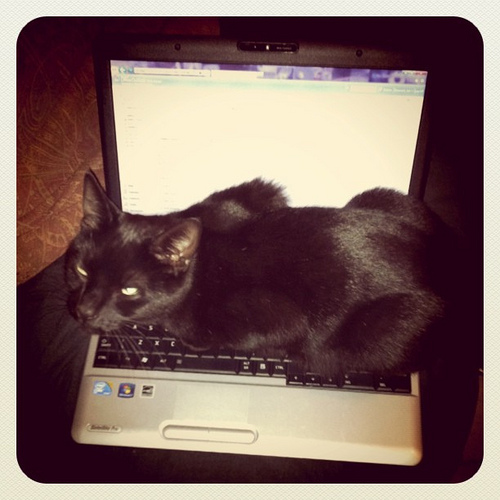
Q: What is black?
A: Cat.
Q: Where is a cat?
A: On laptop computer.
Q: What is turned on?
A: Computer screen.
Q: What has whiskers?
A: The cat.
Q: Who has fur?
A: One cat.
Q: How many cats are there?
A: One.